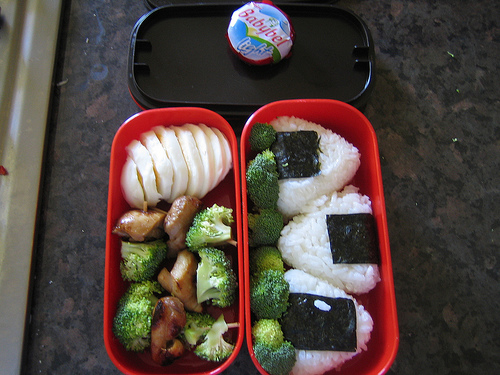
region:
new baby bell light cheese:
[225, 2, 294, 64]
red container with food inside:
[103, 102, 248, 373]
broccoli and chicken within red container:
[116, 210, 233, 362]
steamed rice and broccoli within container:
[253, 122, 374, 372]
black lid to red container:
[123, 0, 380, 105]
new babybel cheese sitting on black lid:
[123, 5, 303, 105]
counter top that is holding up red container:
[61, 107, 496, 370]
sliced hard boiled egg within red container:
[118, 117, 238, 212]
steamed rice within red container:
[296, 101, 387, 367]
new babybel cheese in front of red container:
[228, 4, 388, 371]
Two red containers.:
[97, 92, 414, 368]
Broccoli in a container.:
[235, 95, 400, 370]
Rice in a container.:
[235, 96, 402, 371]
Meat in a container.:
[100, 95, 240, 372]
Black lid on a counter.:
[125, 0, 375, 111]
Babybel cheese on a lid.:
[126, 0, 376, 107]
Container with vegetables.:
[240, 95, 401, 370]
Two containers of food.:
[108, 98, 398, 374]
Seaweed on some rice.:
[276, 186, 376, 291]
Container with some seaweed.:
[241, 96, 404, 371]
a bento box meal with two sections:
[84, 6, 417, 373]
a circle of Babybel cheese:
[221, 3, 305, 75]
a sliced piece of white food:
[116, 119, 235, 203]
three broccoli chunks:
[181, 210, 249, 363]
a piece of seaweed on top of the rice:
[324, 211, 378, 269]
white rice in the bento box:
[279, 191, 328, 292]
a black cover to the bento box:
[301, 3, 387, 98]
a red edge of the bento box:
[86, 116, 113, 357]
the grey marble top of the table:
[397, 71, 478, 311]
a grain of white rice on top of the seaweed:
[312, 293, 334, 320]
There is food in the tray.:
[100, 79, 417, 372]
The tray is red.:
[98, 100, 401, 370]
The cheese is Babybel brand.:
[204, 2, 321, 74]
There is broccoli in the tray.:
[115, 199, 243, 366]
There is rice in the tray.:
[287, 197, 345, 303]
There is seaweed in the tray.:
[277, 285, 366, 358]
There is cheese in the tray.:
[123, 123, 233, 206]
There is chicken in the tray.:
[120, 197, 204, 246]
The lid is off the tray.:
[115, 4, 395, 124]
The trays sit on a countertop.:
[9, 4, 497, 369]